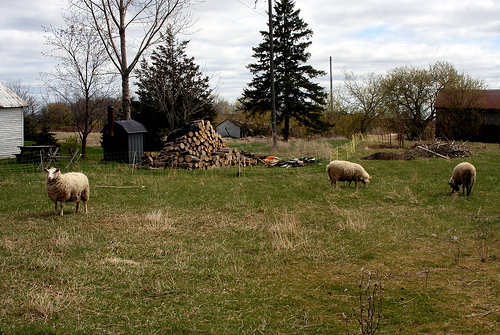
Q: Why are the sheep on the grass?
A: Graze.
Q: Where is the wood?
A: In a pile.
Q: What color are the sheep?
A: White.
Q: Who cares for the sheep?
A: Farmer.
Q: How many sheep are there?
A: Three.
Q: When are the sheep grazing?
A: Daytime.